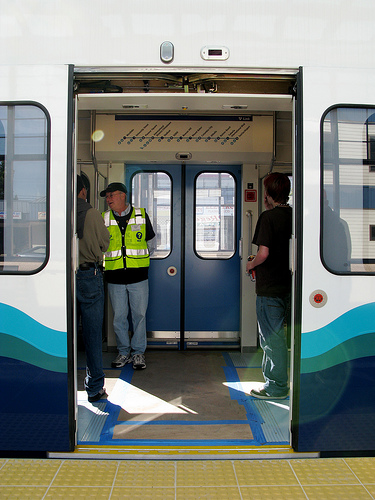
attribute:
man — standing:
[98, 178, 153, 368]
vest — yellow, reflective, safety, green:
[101, 208, 150, 266]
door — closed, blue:
[123, 161, 179, 348]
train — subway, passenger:
[0, 1, 374, 457]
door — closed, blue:
[179, 161, 242, 346]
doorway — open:
[70, 65, 290, 451]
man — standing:
[246, 172, 290, 402]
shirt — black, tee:
[255, 205, 290, 298]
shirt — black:
[101, 211, 156, 284]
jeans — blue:
[105, 283, 154, 352]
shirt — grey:
[76, 198, 111, 266]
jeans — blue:
[76, 269, 107, 393]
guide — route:
[111, 122, 251, 151]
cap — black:
[98, 182, 127, 197]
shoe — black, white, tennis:
[130, 348, 150, 371]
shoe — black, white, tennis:
[111, 348, 129, 370]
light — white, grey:
[157, 41, 178, 64]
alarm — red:
[242, 186, 259, 205]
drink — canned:
[246, 254, 258, 281]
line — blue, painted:
[117, 416, 249, 428]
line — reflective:
[104, 248, 149, 259]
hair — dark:
[264, 169, 292, 204]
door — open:
[2, 65, 77, 452]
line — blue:
[220, 348, 263, 443]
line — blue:
[78, 438, 290, 447]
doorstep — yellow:
[76, 442, 294, 453]